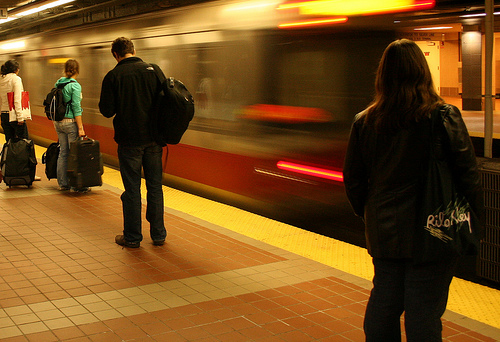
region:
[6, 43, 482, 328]
people at the platform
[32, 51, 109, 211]
girl carrying the suitcases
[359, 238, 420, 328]
leg of a person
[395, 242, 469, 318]
leg of a person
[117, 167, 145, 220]
leg of a person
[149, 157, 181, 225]
leg of a person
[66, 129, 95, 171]
leg of a person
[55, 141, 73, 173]
leg of a person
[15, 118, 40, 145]
leg of a person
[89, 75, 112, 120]
arm of a person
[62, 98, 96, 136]
arm of a person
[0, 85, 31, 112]
arm of a person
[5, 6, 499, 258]
the train is moving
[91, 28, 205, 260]
boy holding a black backpack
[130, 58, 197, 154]
the backpack is black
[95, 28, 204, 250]
person wearing black clothes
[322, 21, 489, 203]
woman has long hair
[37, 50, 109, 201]
woman holding two suitcases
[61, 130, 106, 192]
the suitcase is color black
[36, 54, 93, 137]
woman holding a black backpack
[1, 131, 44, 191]
a black suitcase on the ground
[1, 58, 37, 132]
woman wears white top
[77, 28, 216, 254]
Man standing on the sidewalk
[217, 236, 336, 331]
The sidewalk is made of tile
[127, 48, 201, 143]
Man holding a backpack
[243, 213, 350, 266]
yellow paint on the sidewalk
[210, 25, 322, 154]
The train is speeding past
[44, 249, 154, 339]
Sidewalk is made of tile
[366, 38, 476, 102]
Woman has long dark hair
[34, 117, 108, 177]
Woman carrying some luggage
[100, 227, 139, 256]
Man is wearing tennis shoes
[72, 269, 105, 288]
Cracks between the pavement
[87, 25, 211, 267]
The man is waiting for the train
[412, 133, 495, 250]
Woman is carrying a bag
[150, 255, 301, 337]
Tiles on the ground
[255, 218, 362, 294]
Yellow paint on the pavement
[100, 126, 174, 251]
Man is wearing pants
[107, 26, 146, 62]
Man has short brown hair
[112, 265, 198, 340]
Line painted on the pavement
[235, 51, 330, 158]
The bus is moving quickly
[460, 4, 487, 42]
Light shining on the train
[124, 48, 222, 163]
Man is holding a backpack